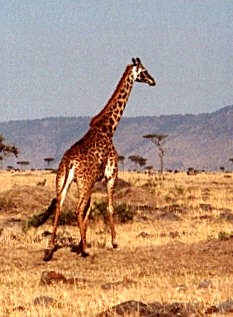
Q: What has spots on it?
A: Giraffe.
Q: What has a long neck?
A: Giraffe.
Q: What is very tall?
A: Giraffe.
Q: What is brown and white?
A: Giraffe.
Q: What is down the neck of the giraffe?
A: Stripe of hair.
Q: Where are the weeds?
A: On the ground.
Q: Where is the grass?
A: On the ground.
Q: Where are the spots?
A: On the ground.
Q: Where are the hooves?
A: On the giraffe.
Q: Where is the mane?
A: On the giraffe.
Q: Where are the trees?
A: In the field.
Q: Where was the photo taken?
A: African plains.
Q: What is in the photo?
A: Giraffe.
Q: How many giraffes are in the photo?
A: One.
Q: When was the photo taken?
A: Daytime.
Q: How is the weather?
A: Sunny.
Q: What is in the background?
A: Hills.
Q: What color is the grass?
A: Yellow.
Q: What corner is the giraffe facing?
A: Upper right.